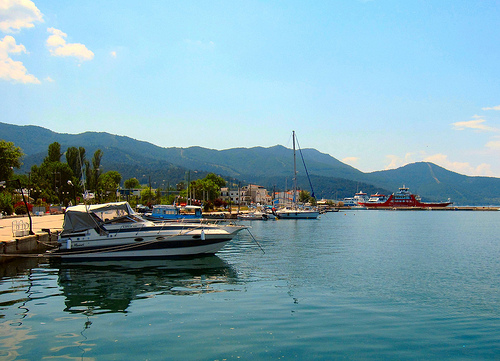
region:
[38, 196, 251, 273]
Speed boat in the water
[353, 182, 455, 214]
Long red colored ship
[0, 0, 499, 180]
Blue sky with few clouds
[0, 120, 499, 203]
Long range of hills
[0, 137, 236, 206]
Vegetation of lush green trees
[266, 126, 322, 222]
Boat with a tall mast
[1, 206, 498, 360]
Expanse of blue water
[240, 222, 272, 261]
Anchor cable going into the water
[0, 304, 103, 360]
White shadows in the water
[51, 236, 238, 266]
Striped colored body of a boat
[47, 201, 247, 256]
cabin cruiser at dock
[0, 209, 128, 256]
floating dock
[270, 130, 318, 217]
tall-masted sailboat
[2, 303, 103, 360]
oil slick in water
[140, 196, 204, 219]
white and blue boat cabin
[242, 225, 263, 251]
anchor chain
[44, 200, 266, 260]
boat tied stern first to dock to ropes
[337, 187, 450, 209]
large boats at dock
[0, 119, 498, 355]
sunny dat at harbor surrounded by mountains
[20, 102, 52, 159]
This is a mountain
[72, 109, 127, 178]
This is a mountain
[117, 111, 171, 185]
This is a mountain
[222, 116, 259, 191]
This is a mountain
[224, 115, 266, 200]
This is a mountain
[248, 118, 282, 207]
This is a mountain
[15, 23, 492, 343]
Some boats are parked at a dock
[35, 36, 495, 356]
Some boats are floating in the water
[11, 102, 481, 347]
Some boats are waiting for their owners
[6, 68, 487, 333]
Some boats are close to the shore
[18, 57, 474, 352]
Some boats are tied up by anchor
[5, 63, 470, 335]
Some boats are used for fishing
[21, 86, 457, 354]
The boats are out in the sunshine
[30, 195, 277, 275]
A docked boat in calm water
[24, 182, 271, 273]
A docked boat in calm water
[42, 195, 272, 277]
A docked boat in calm water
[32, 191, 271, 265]
A docked boat in calm water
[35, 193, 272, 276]
A docked boat in calm water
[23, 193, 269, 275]
A docked boat in calm water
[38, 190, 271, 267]
A docked boat in calm water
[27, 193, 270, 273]
A docked boat in calm water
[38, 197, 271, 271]
A docked boat in calm water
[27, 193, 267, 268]
A docked boat in calm water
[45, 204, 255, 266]
a boat on the water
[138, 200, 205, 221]
a boat on the water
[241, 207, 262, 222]
a boat on the water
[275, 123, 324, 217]
a boat on the water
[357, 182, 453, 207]
a boat on the water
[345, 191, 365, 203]
a boat on the water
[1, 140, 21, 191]
a tree in a field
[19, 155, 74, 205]
a tree in a field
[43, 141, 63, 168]
a tree in a field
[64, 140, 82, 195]
a tree in a field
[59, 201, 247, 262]
small wooden white boat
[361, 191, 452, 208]
large red metal boat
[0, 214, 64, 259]
large wide wooden dock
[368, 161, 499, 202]
large wide tall mountain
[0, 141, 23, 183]
large tall green tree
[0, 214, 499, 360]
large wide open body of water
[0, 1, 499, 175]
large wide open sky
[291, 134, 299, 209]
tall brown wooden mast